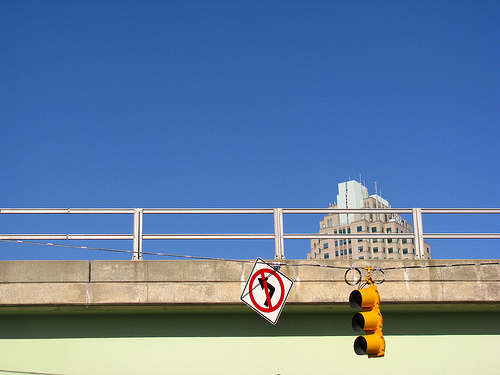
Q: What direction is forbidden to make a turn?
A: Left.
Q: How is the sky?
A: Sky is a deep blue.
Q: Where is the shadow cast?
A: On side of bridge.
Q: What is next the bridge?
A: Building with lots of windows.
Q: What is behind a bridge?
A: Large commercial building.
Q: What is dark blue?
A: The clear sky.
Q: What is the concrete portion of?
A: A city bridge.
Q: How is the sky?
A: Blue and cloudless.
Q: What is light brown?
A: The bridge.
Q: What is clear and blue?
A: The sky.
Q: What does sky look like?
A: Bright blue.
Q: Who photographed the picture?
A: A person.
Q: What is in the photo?
A: A traffic light.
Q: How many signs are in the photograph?
A: One.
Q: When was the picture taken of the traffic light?
A: Daytime.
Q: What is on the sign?
A: No left turn symbol.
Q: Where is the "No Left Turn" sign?
A: On the side of a bridge.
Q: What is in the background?
A: A building.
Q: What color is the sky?
A: Blue.